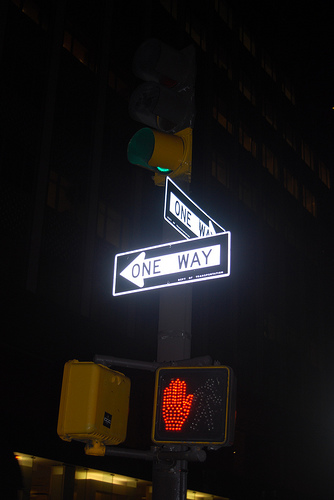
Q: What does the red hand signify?
A: Don't walk.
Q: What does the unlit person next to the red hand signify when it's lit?
A: Walk.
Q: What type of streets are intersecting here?
A: One-way streets.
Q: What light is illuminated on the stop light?
A: Green.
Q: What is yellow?
A: Back of cross walk sign.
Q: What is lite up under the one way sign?
A: A hand.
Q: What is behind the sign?
A: A building.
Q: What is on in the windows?
A: Lights.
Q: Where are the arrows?
A: On the black signs.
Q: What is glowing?
A: The one way signs.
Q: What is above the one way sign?
A: A green light.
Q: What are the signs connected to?
A: A pole.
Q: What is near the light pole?
A: A building.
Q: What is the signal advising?
A: Don't walk.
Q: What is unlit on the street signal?
A: The walking pedestrian.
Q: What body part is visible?
A: Hand.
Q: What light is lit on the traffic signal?
A: Green.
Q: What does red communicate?
A: Do not proceed.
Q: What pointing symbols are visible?
A: Arrows.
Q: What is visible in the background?
A: Building.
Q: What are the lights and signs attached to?
A: Metal pole.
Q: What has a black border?
A: The one way signs.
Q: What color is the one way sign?
A: Black.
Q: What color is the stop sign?
A: Red.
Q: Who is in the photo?
A: No one.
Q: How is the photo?
A: Clear.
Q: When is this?
A: Nighttime.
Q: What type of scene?
A: Outdoor.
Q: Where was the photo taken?
A: In a street.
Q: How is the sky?
A: Dark.